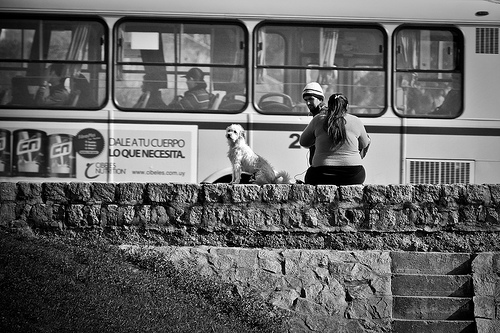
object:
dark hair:
[323, 92, 349, 148]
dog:
[223, 121, 292, 186]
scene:
[1, 2, 500, 332]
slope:
[2, 223, 295, 332]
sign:
[0, 123, 202, 183]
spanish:
[105, 135, 190, 161]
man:
[298, 81, 328, 119]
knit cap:
[298, 80, 326, 97]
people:
[166, 64, 221, 114]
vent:
[402, 154, 480, 186]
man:
[33, 60, 74, 109]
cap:
[180, 66, 207, 80]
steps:
[385, 246, 480, 272]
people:
[296, 94, 373, 187]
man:
[168, 62, 217, 115]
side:
[0, 103, 500, 188]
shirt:
[298, 110, 372, 171]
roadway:
[107, 237, 500, 260]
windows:
[0, 10, 107, 109]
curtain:
[64, 23, 96, 75]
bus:
[2, 2, 499, 191]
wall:
[0, 180, 500, 333]